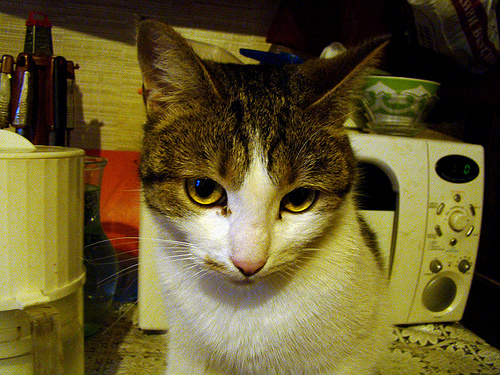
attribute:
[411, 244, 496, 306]
button — grey , large 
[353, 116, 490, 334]
microwave oven — white 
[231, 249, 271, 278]
nose — pink 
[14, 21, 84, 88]
grater — silver 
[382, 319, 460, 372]
flowers — lace table cloth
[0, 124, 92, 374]
water pitcher — White 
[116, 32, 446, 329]
cat — yellow , bright 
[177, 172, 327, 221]
eyes — yellow, cat's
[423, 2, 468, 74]
bread bag — plastic 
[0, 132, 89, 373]
processor — plastic, dirty, white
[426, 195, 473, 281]
buttons — microwave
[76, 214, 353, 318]
whiskers — cat's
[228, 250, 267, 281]
nose — pink 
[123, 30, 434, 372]
cat — white gray and black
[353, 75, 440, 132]
bowl — green 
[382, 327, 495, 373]
counter — non-slip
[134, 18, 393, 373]
cat — cute, white, tabby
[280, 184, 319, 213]
eye — yellow 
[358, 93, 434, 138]
bowl — plastic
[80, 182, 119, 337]
liquid — blue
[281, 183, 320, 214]
eye — amber, runny, cat's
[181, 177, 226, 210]
eye — amber, runny, cat's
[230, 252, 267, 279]
nose — cat's, small, pale, pink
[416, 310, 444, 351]
table cloth — white 